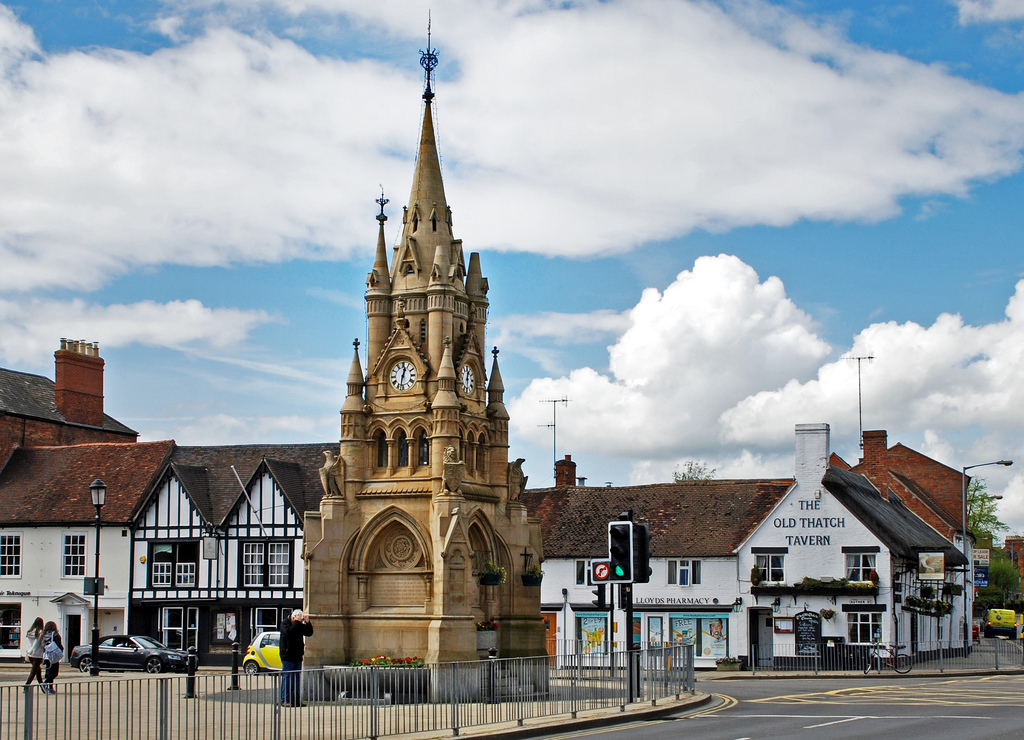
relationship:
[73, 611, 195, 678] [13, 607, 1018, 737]
car in street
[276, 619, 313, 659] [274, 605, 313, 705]
jacket on a man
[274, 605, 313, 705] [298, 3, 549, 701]
man in front of clock tower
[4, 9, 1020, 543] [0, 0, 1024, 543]
clouds in clouds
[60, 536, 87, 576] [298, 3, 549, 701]
window facing clock tower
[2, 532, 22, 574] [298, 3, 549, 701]
window facing clock tower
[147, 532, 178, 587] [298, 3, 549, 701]
window facing clock tower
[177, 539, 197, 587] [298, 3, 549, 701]
window facing clock tower